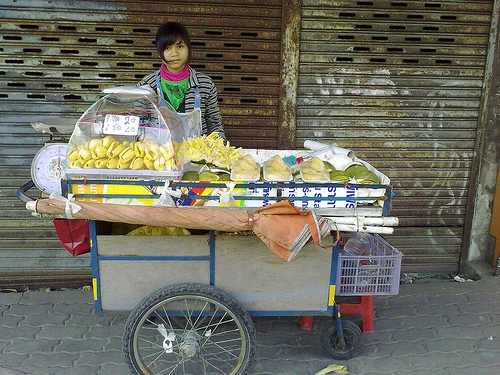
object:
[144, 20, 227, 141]
woman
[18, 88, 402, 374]
food cart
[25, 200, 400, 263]
umbrella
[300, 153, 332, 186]
food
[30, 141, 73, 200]
scale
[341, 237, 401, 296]
basket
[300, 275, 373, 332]
stool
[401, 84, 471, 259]
graffiti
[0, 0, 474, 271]
wall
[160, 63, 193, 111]
scarf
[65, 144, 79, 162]
bananas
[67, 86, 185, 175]
dome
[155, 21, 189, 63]
hair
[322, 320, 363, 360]
front wheel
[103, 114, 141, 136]
tag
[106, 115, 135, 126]
price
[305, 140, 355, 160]
paper towel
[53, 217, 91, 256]
bag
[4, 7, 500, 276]
building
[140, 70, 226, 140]
shirt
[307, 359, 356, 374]
trash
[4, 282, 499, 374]
sidewalk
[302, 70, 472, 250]
painting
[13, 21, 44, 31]
holes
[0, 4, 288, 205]
siding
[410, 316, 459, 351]
stones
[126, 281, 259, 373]
wheel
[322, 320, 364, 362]
wheel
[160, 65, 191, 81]
fabric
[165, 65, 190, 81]
neck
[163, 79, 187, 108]
fabric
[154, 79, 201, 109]
chest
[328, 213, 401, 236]
pole